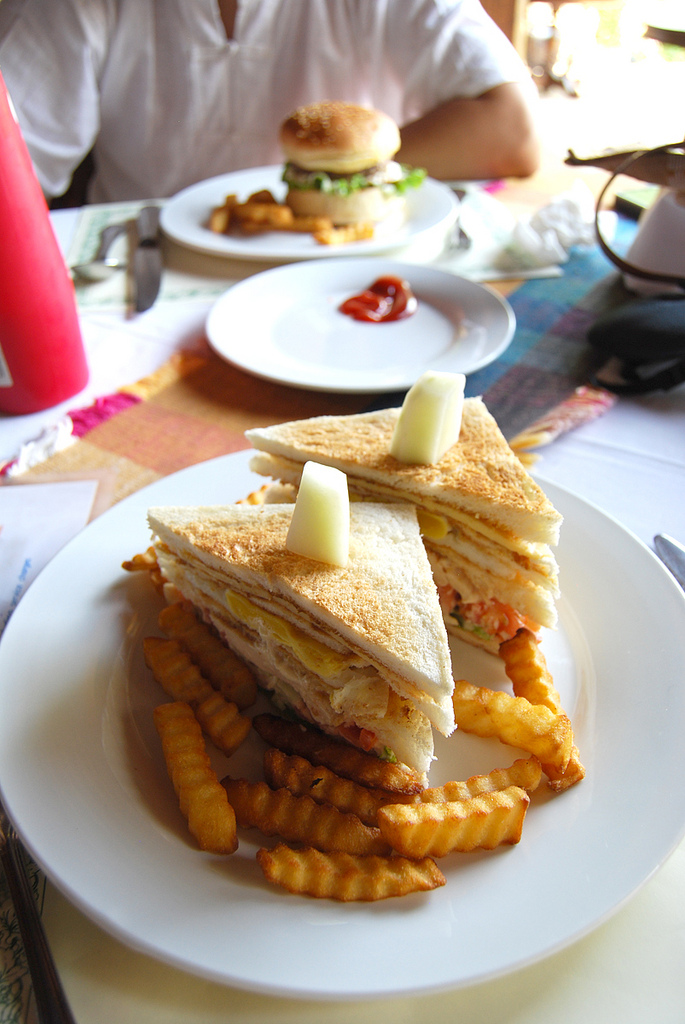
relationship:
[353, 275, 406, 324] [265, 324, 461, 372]
ketchup on top of plate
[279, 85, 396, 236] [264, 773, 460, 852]
bun and fries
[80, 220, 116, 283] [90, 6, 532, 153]
spoon in front of man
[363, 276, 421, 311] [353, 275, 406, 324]
glob of ketchup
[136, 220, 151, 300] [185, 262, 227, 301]
knife on top of place mat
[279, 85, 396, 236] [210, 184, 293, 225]
bun and french fries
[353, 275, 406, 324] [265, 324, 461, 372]
ketchup on plate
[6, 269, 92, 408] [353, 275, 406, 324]
bottle of ketchup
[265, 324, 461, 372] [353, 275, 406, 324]
plate used for ketchup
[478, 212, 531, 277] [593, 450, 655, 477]
napkin on top of table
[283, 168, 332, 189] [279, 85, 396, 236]
lettuce inside of bun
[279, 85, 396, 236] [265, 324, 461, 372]
bun on top of plate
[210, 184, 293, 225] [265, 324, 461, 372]
french fries on top of plate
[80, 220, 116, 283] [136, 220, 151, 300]
spoon next to knife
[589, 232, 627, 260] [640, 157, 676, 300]
strap attached to bag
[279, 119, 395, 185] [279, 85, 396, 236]
bun attached to bun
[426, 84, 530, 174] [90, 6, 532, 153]
elbow attached to man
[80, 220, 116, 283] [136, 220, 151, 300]
spoon and knife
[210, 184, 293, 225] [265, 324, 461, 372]
french fries on plate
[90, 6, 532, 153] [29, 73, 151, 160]
man wearing shirt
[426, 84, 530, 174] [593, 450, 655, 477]
elbow on top of table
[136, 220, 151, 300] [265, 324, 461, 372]
knife next to plate